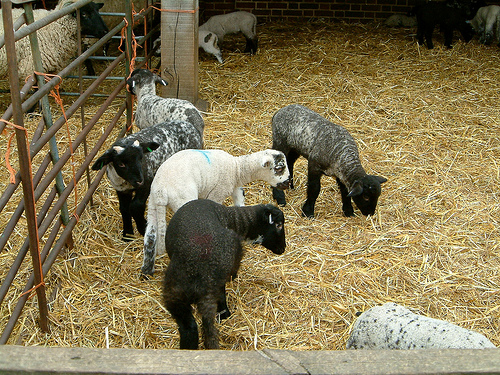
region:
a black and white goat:
[88, 118, 189, 243]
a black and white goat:
[270, 105, 386, 221]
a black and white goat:
[164, 195, 290, 347]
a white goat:
[138, 144, 288, 277]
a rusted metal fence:
[2, 1, 159, 346]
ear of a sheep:
[140, 142, 160, 153]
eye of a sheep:
[115, 160, 125, 167]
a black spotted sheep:
[341, 303, 491, 350]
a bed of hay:
[0, 24, 499, 346]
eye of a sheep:
[362, 193, 371, 202]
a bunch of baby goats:
[104, 69, 375, 311]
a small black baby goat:
[168, 202, 293, 287]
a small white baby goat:
[160, 139, 317, 193]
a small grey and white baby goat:
[121, 83, 216, 131]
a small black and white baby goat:
[101, 126, 179, 191]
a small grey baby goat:
[261, 98, 398, 222]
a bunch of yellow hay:
[378, 106, 489, 224]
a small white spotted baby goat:
[344, 285, 484, 362]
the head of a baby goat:
[334, 148, 394, 216]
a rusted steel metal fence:
[1, 78, 83, 195]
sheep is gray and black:
[268, 107, 387, 224]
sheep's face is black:
[353, 176, 393, 216]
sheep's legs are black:
[267, 144, 361, 224]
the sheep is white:
[122, 142, 290, 279]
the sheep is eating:
[262, 102, 384, 223]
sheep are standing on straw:
[4, 3, 497, 368]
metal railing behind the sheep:
[1, 6, 173, 347]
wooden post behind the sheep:
[149, 3, 210, 101]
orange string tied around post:
[106, 3, 198, 128]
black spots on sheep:
[263, 151, 289, 177]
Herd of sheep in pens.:
[2, 1, 499, 352]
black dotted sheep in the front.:
[345, 295, 496, 349]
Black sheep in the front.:
[162, 193, 291, 351]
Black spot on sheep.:
[200, 27, 222, 62]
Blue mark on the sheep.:
[188, 136, 220, 165]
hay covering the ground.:
[1, 23, 496, 349]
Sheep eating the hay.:
[268, 102, 395, 227]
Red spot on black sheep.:
[190, 227, 217, 262]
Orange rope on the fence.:
[2, 68, 99, 308]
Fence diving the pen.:
[3, 0, 165, 341]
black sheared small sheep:
[186, 210, 259, 285]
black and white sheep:
[344, 316, 409, 338]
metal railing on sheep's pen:
[16, 115, 56, 218]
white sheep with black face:
[178, 148, 215, 198]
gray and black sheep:
[130, 123, 151, 165]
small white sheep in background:
[198, 30, 217, 56]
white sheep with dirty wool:
[52, 15, 92, 60]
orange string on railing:
[38, 69, 73, 104]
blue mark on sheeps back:
[183, 143, 233, 170]